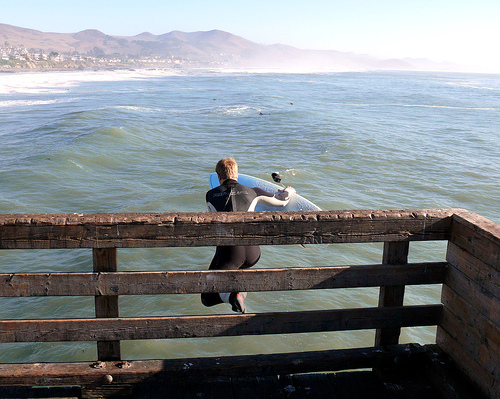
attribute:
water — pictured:
[1, 71, 497, 363]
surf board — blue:
[209, 173, 223, 187]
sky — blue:
[282, 2, 497, 60]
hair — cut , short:
[212, 153, 239, 180]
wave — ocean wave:
[75, 102, 194, 115]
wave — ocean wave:
[213, 102, 256, 117]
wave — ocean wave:
[1, 95, 73, 108]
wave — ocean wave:
[1, 66, 260, 93]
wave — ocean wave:
[437, 75, 499, 94]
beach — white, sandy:
[0, 66, 494, 78]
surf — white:
[5, 65, 359, 82]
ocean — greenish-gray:
[51, 81, 441, 171]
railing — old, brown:
[2, 220, 499, 362]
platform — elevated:
[28, 377, 468, 396]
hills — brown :
[29, 12, 279, 117]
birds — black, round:
[187, 82, 314, 118]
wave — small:
[2, 77, 179, 266]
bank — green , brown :
[15, 59, 104, 72]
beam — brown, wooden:
[3, 210, 451, 250]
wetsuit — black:
[202, 180, 298, 310]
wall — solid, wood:
[432, 202, 488, 391]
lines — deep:
[47, 227, 450, 243]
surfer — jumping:
[199, 160, 299, 310]